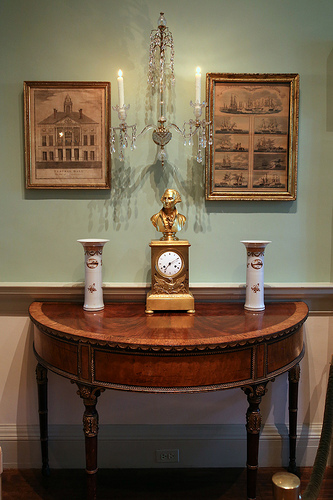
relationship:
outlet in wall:
[154, 448, 179, 463] [2, 0, 331, 468]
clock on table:
[147, 239, 196, 314] [29, 299, 311, 491]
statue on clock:
[151, 188, 189, 240] [147, 239, 196, 314]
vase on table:
[241, 239, 272, 312] [29, 299, 311, 491]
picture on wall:
[205, 71, 298, 205] [2, 0, 331, 468]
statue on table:
[151, 188, 189, 240] [29, 299, 311, 491]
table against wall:
[29, 299, 311, 491] [2, 0, 331, 468]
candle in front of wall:
[117, 70, 126, 106] [2, 0, 331, 468]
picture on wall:
[21, 80, 111, 191] [2, 0, 331, 468]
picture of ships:
[205, 71, 298, 205] [220, 94, 280, 115]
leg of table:
[34, 366, 49, 480] [29, 299, 311, 491]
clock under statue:
[147, 239, 196, 314] [151, 188, 189, 240]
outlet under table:
[154, 448, 179, 463] [29, 299, 311, 491]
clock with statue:
[147, 239, 196, 314] [151, 188, 189, 240]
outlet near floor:
[154, 448, 179, 463] [0, 468, 333, 498]